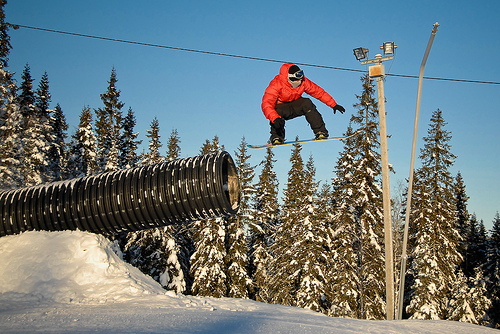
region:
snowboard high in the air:
[241, 63, 363, 153]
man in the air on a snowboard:
[247, 58, 357, 150]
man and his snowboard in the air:
[242, 59, 356, 152]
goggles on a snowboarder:
[286, 68, 305, 82]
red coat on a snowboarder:
[258, 61, 336, 122]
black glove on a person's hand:
[331, 103, 343, 113]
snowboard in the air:
[244, 134, 359, 151]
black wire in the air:
[2, 21, 499, 86]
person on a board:
[243, 60, 358, 146]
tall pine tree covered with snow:
[324, 67, 406, 319]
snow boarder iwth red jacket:
[249, 54, 351, 148]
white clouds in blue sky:
[11, 9, 51, 66]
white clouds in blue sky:
[47, 7, 95, 61]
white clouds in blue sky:
[121, 34, 168, 78]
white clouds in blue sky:
[159, 53, 213, 111]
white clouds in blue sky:
[247, 17, 292, 45]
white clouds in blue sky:
[384, 19, 425, 39]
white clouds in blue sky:
[444, 27, 481, 57]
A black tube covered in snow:
[7, 150, 235, 235]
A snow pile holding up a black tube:
[5, 222, 161, 298]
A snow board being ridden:
[243, 132, 360, 148]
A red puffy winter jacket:
[256, 56, 337, 131]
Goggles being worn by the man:
[288, 68, 307, 80]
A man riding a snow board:
[238, 55, 345, 152]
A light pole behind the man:
[338, 42, 411, 322]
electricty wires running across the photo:
[0, 12, 490, 115]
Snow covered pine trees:
[5, 25, 493, 308]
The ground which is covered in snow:
[10, 227, 454, 328]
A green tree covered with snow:
[404, 113, 496, 328]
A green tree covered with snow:
[343, 71, 391, 311]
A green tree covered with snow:
[290, 146, 319, 297]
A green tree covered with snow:
[258, 137, 298, 307]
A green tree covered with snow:
[187, 137, 257, 312]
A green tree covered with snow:
[140, 88, 214, 277]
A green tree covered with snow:
[81, 63, 156, 214]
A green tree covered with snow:
[10, 55, 92, 330]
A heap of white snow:
[11, 227, 128, 303]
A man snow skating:
[235, 54, 347, 141]